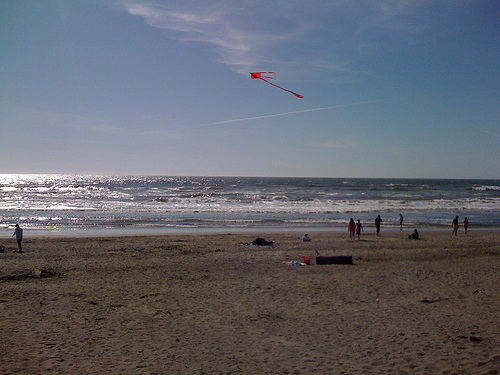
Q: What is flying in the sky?
A: Kite.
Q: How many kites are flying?
A: 1.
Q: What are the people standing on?
A: Sand.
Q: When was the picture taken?
A: Day time.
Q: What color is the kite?
A: Red.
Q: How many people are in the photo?
A: 8.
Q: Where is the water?
A: In front of the people.